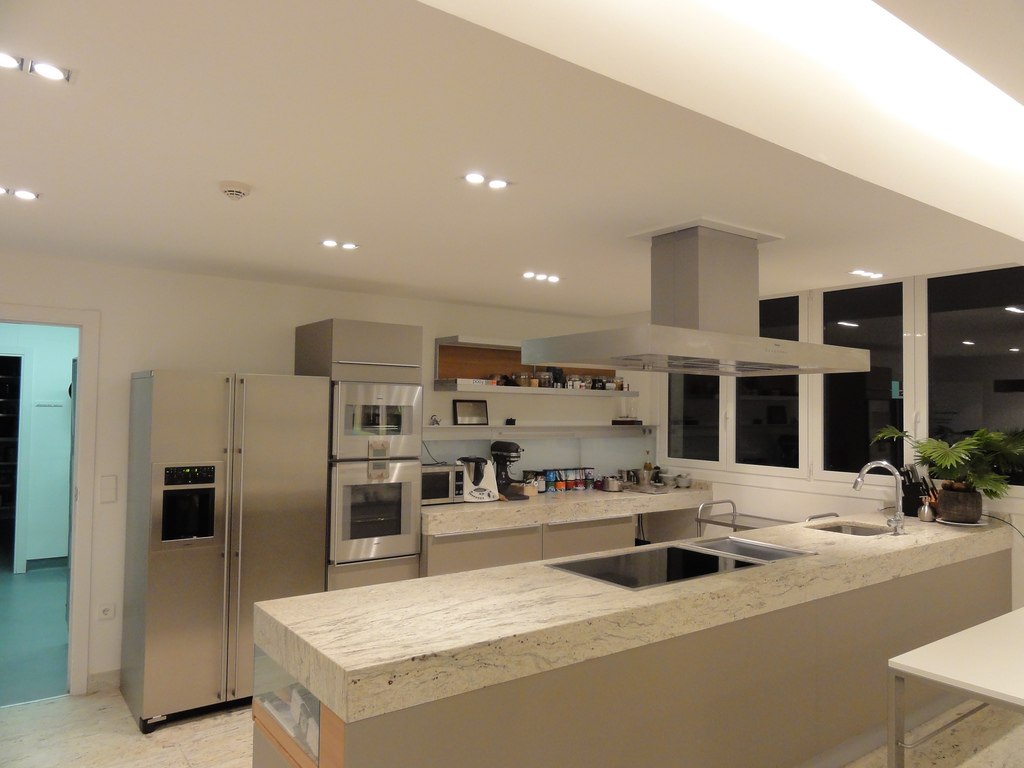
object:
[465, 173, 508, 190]
light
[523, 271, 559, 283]
light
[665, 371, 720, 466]
window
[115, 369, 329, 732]
refrigerator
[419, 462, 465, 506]
microwave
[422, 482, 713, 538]
countertop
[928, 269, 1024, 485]
window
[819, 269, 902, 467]
window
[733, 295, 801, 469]
window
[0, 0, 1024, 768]
kitchen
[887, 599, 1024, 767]
table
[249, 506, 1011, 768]
island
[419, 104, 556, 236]
ceiling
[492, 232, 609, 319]
ceiling